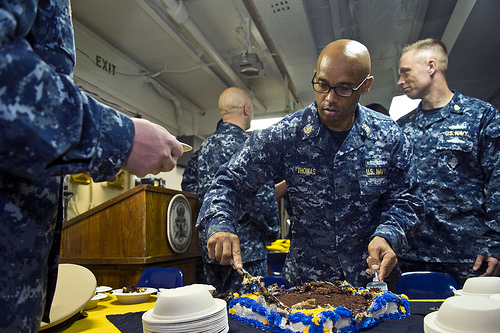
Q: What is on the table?
A: Cake.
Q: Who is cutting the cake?
A: The man wearing glasses.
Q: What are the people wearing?
A: Military uniforms.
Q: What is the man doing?
A: Cutting a cake.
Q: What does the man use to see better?
A: Glasses.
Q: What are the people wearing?
A: Military uniforms.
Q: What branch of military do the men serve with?
A: The navy.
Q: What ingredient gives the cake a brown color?
A: Chocolate.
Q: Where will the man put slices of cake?
A: In the bowls.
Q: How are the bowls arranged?
A: In stacks.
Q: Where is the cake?
A: On the table.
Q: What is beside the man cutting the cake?
A: A podium.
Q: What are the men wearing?
A: Uniforms.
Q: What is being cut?
A: A cake.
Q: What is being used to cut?
A: A knife.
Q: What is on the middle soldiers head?
A: Glasses.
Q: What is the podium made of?
A: Wood.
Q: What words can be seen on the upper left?
A: EXIT.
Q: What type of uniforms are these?
A: Navy uniforms.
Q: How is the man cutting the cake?
A: Knife.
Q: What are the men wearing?
A: Camouflage.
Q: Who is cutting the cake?
A: Man with glasses.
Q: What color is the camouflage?
A: Blue.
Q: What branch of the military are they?
A: Navy.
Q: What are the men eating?
A: Cake.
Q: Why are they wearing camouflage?
A: Military.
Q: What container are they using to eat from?
A: Bowls.